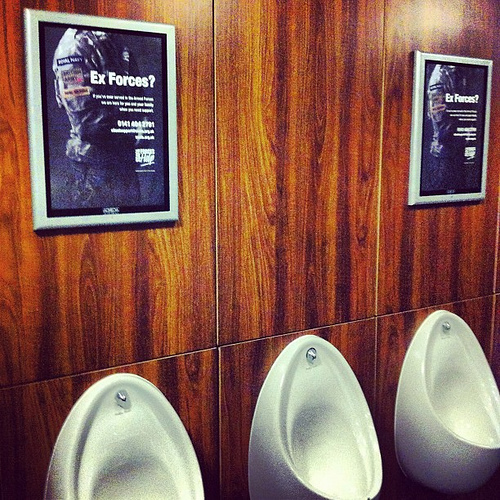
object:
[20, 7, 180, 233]
advertisement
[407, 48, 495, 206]
ad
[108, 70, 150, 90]
words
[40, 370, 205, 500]
urinals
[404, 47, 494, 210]
silver frame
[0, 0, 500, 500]
wall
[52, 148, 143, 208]
body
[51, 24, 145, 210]
man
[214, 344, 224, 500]
line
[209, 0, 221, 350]
line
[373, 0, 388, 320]
line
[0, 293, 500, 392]
line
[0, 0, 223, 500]
two panels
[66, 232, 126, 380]
wood grain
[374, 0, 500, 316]
panel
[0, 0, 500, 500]
bathroom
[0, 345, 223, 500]
wood panels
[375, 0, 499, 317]
wood panels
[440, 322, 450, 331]
shiny metal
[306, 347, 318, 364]
shiny metal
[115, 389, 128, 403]
shiny metal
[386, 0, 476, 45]
light reflection